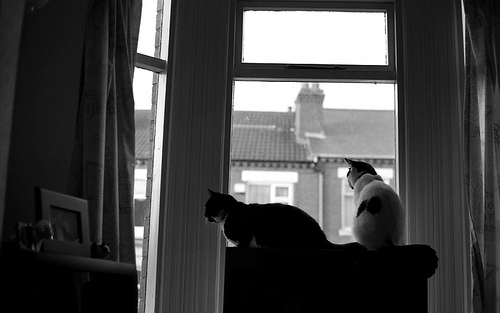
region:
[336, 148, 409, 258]
White and black cat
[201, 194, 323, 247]
Black and white cat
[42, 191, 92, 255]
Picture on the shelf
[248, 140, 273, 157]
Gray roof on the neighbor's house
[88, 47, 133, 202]
Curtains for the window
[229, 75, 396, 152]
Top section of the window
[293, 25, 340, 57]
Small patch of the overcast sky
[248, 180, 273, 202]
One of the windows from the neighbors house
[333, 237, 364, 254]
Tail of the black and white cat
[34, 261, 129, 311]
Black shelf in the house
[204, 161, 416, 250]
cats sitting in a window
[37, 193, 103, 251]
picture frame on table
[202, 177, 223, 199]
ear on a cat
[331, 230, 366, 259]
tail on the cat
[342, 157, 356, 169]
ear on the cat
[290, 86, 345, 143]
chimney on the roof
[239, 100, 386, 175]
building outside the window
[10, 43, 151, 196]
curtain on the window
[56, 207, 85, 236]
picture in picture frame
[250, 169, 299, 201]
window on building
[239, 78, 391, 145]
window with open curtains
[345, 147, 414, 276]
white and black cat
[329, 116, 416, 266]
white and black cat looking out of window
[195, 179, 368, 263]
black cat laying down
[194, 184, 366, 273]
black cat looking out of window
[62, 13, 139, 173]
curtain by window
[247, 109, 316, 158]
slanted roof of house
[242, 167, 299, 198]
white frame on window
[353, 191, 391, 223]
black spots on cat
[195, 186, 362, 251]
a sitting black cat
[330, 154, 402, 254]
a sitting black and white cat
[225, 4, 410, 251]
a large outdoor window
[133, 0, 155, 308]
a large outdoor window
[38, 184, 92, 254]
a picture frame with photo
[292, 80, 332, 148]
a tall brick chimney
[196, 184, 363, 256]
a black cat looking out of window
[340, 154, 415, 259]
a standing cat looking out window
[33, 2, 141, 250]
cloth drapery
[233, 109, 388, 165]
a tiled roof in distance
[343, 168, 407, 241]
the cat is black and white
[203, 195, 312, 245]
the cat is black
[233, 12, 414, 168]
the window is open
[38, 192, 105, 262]
the frame is wooden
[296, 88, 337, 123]
the chimney is made of bricks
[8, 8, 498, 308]
the photo was taken indoors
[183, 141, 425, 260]
two cats are on the cupboard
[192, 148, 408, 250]
the cats are looking outside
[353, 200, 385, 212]
black spots are on the cat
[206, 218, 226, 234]
the whiskers are white